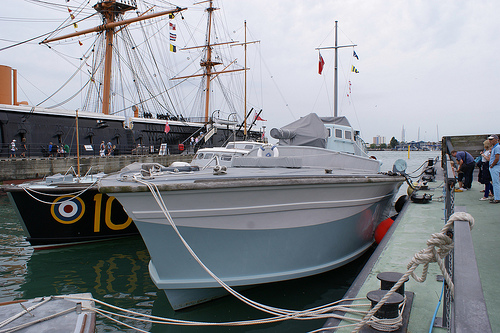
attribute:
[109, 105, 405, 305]
ship — front part 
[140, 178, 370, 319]
thread — strong white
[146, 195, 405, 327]
thread —  steamer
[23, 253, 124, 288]
water — dark blue.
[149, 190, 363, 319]
ropes — white 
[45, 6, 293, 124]
wires — electricity , bunch 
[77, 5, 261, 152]
pole — different flags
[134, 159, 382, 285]
boat — white, blue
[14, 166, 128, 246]
boat — yellow , black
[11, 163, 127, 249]
boat — black, 10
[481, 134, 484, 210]
man — light blue pants.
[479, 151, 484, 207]
woman — l white shoes.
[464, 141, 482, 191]
man — black pants.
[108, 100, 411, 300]
boat — white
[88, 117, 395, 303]
boat — white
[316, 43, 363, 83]
flags — small different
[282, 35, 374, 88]
flags — small different 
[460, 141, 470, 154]
man — head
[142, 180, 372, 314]
rope — white 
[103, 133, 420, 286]
boat — bow 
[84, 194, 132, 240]
boat — yellow number  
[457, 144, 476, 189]
man — arm  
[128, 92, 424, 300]
ship — mast 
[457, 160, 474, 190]
legs — male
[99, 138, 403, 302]
boat — one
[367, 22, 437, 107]
sky — cloudy, gray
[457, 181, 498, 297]
dock — one